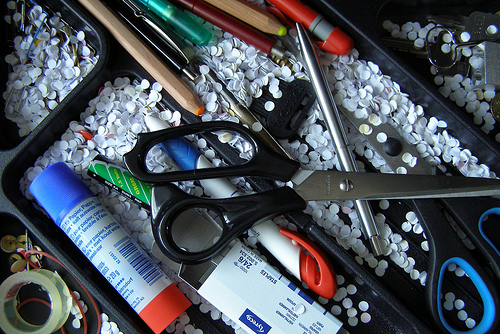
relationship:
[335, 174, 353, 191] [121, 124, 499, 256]
screw on scissors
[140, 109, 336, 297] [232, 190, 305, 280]
inkpen with barrel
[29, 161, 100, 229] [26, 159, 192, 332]
cap on glue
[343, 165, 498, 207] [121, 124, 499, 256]
blade of scissors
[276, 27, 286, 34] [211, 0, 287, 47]
lead of pencil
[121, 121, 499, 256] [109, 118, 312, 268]
scissors with handle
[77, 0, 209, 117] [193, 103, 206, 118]
pencil with a orange tip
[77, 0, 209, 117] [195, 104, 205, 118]
pencil with a tip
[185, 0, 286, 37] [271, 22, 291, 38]
pencil with a tip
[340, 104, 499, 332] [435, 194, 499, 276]
scissors with a handle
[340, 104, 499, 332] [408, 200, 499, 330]
scissors with a handle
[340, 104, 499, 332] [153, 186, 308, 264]
scissors with a handle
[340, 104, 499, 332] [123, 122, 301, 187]
scissors with a handle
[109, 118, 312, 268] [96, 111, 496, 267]
handle on scissors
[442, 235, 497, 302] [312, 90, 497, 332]
handle on scissors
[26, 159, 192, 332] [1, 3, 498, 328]
glue in a tray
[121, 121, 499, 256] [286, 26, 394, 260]
scissors above pen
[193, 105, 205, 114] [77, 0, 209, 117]
lead side of pencil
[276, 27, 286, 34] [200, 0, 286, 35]
lead side of pencil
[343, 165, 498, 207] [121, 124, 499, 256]
blade on scissors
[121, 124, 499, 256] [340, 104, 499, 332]
scissors next to scissors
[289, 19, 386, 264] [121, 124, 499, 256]
pen below scissors